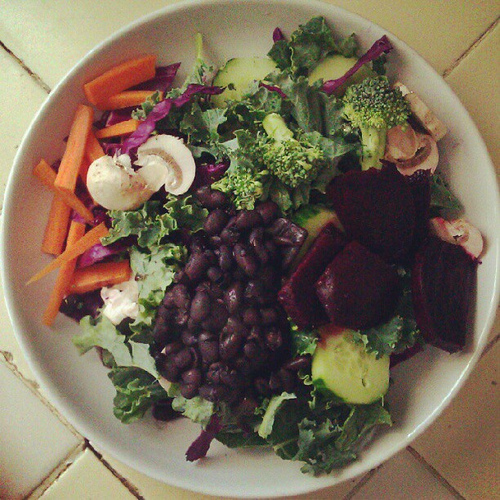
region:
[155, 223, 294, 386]
the beans are black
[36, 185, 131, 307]
the carrots are orange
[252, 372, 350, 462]
the lettice is green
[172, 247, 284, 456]
beans on the lettuce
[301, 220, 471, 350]
the cranberry is red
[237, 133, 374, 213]
the broccoli is green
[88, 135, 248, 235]
the mushrooms are white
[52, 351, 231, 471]
the plate is white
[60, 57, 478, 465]
the vegetables on plate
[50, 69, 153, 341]
the carrots on the plate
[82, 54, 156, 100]
orange carrot stick next to carrot stick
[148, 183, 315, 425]
black beans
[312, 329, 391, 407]
green cucumber next to beet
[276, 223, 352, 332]
beet on top of cucumber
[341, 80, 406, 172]
broccoli floret to the left of mushroom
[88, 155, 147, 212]
white mushroom on top of carrot stick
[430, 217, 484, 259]
mushroom under beet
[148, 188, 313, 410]
black beans next to beet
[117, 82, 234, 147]
red cabbage con top of lettuce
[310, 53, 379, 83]
cucumber under red cabbage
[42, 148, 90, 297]
Orange cut pieces of carrot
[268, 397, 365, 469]
Green leafy lettuce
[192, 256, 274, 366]
bunch of dark beans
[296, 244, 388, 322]
pair of dark red beets.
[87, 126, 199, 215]
Raw sliced white mushrooms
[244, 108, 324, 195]
Piece of green broccoli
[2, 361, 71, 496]
white tile with grime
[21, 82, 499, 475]
Fresh veggie salad in white bowl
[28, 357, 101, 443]
corner of white bowl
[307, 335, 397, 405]
green cucumber with seeds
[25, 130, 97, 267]
orange carrots on plate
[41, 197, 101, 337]
orange carrots on plate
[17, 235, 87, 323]
orange carrots on plate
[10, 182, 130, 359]
orange carrots on plate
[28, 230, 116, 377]
orange carrots on plate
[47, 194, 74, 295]
orange carrots on plate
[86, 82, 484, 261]
Mushrooms in the salad.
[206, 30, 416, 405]
Cucumber in the salad.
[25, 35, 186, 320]
Carrot sticks in the salad.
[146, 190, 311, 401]
Black beans in the salad.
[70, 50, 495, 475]
Greens in a salad.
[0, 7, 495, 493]
Salad on a white plate.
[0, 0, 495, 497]
Tile countertop on which plate sits.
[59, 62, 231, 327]
Red cabbage on the plate.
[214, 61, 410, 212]
Broccoli on the plate.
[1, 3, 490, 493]
Large healthy salad on a plate.